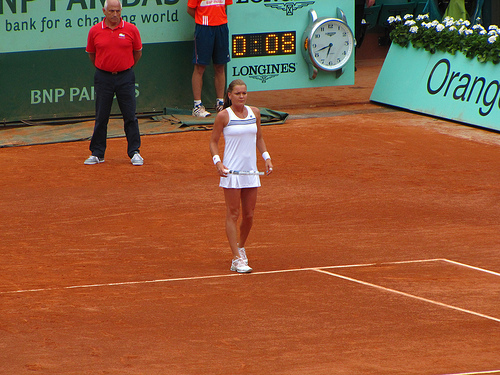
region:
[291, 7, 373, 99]
a clock on a tennis court.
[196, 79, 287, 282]
a woman holding a racket.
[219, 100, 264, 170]
a shirt on a tennis player.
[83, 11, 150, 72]
a red t shirt.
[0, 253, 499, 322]
lines on a tennis court.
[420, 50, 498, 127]
orange on a sign.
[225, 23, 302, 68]
a number on a clock.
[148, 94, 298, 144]
a platform on a tennis court.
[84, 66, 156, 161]
a black pair of pants.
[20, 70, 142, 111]
writing on a wall.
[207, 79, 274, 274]
A woman wearing all white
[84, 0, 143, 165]
An older man wearing a red shirt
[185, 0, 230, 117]
Part of a person wearing orange and blue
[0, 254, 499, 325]
Chalk lines painted in dirt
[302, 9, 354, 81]
A silver and white analog clock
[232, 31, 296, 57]
A black and orange digital timer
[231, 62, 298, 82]
A Longines logo on a wall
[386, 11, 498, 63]
A row of white flowers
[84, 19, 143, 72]
A men's red shirt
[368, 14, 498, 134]
Part of a wall with flowers on top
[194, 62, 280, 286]
a woman holding a tennis racket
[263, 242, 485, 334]
white lines on a tennis court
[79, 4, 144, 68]
a man wearing a red shirt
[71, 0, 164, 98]
a man standing with his hands behind him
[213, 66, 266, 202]
a woman wearing a white tennis dress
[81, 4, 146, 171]
a man wearing black pants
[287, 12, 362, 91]
a silver clock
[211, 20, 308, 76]
a digital timer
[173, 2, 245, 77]
a person wearing blue shorts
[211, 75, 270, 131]
a woman with her hair pulled back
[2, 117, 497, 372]
a brown tennis court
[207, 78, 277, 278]
a female tennis player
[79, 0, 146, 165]
a man standing on tennis court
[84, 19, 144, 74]
red short sleeve shirt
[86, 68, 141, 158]
pair of blue men's pants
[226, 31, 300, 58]
a digital clock sign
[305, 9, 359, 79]
an analog watch sign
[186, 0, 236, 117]
man standing at edge of court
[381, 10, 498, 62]
a row of white flowers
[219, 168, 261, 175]
a white tennis racket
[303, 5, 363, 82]
Silver and white mounted clock.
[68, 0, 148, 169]
Man standing on the outside of the court.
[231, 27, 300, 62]
Black and orange timer.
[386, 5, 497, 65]
White flowers atop green box.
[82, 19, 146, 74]
Man's red polo shirt.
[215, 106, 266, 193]
White and blue tennis dress.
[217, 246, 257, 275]
Woman's white tennis shoes.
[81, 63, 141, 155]
Man's blue slacks and black belt.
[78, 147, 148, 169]
Man's blue tennis shoes.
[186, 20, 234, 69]
Mans blue sport shorts.